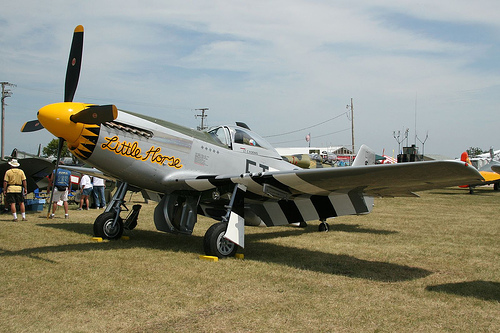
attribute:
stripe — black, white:
[188, 171, 372, 222]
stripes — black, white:
[180, 169, 379, 232]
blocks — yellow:
[85, 232, 251, 271]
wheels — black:
[82, 193, 244, 267]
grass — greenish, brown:
[1, 147, 500, 326]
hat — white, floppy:
[6, 156, 24, 170]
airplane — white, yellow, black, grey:
[10, 20, 495, 271]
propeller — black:
[14, 17, 122, 142]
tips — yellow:
[59, 22, 94, 44]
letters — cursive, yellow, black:
[89, 131, 188, 172]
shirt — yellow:
[2, 167, 27, 195]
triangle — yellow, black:
[74, 97, 102, 161]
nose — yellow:
[23, 96, 105, 147]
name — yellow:
[93, 135, 197, 167]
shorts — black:
[2, 187, 28, 207]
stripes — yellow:
[74, 95, 103, 161]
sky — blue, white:
[2, 0, 499, 172]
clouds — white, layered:
[137, 1, 492, 75]